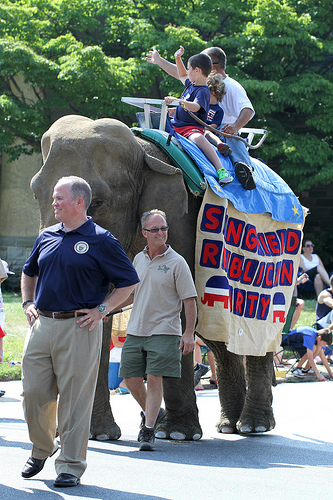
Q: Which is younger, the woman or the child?
A: The child is younger than the woman.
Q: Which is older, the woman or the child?
A: The woman is older than the child.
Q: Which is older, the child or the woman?
A: The woman is older than the child.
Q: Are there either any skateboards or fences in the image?
A: No, there are no fences or skateboards.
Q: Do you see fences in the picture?
A: No, there are no fences.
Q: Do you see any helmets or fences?
A: No, there are no fences or helmets.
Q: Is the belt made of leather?
A: Yes, the belt is made of leather.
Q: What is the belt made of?
A: The belt is made of leather.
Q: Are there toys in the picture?
A: No, there are no toys.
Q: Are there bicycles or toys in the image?
A: No, there are no toys or bicycles.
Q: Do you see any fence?
A: No, there are no fences.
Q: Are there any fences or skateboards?
A: No, there are no fences or skateboards.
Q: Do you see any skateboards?
A: No, there are no skateboards.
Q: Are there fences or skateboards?
A: No, there are no skateboards or fences.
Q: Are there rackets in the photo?
A: No, there are no rackets.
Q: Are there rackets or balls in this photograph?
A: No, there are no rackets or balls.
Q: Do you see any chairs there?
A: Yes, there is a chair.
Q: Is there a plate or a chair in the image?
A: Yes, there is a chair.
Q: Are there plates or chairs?
A: Yes, there is a chair.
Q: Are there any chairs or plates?
A: Yes, there is a chair.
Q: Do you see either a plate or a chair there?
A: Yes, there is a chair.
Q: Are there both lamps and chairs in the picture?
A: No, there is a chair but no lamps.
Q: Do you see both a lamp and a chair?
A: No, there is a chair but no lamps.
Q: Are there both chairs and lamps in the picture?
A: No, there is a chair but no lamps.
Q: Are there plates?
A: No, there are no plates.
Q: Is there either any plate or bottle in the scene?
A: No, there are no plates or bottles.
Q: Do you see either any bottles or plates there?
A: No, there are no plates or bottles.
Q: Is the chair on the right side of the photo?
A: Yes, the chair is on the right of the image.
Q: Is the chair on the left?
A: No, the chair is on the right of the image.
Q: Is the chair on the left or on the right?
A: The chair is on the right of the image.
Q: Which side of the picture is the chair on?
A: The chair is on the right of the image.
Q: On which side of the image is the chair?
A: The chair is on the right of the image.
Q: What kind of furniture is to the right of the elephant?
A: The piece of furniture is a chair.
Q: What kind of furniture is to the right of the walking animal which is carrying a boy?
A: The piece of furniture is a chair.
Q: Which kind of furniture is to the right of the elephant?
A: The piece of furniture is a chair.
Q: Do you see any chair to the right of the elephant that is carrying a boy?
A: Yes, there is a chair to the right of the elephant.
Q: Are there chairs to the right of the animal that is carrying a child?
A: Yes, there is a chair to the right of the elephant.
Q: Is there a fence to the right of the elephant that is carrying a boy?
A: No, there is a chair to the right of the elephant.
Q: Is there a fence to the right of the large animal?
A: No, there is a chair to the right of the elephant.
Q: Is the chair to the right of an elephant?
A: Yes, the chair is to the right of an elephant.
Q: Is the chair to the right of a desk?
A: No, the chair is to the right of an elephant.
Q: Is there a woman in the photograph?
A: Yes, there is a woman.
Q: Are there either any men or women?
A: Yes, there is a woman.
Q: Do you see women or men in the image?
A: Yes, there is a woman.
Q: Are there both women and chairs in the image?
A: Yes, there are both a woman and a chair.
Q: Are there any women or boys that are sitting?
A: Yes, the woman is sitting.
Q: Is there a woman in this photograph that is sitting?
A: Yes, there is a woman that is sitting.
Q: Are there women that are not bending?
A: Yes, there is a woman that is sitting.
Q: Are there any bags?
A: No, there are no bags.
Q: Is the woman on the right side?
A: Yes, the woman is on the right of the image.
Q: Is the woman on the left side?
A: No, the woman is on the right of the image.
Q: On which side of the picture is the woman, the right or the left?
A: The woman is on the right of the image.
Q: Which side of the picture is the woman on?
A: The woman is on the right of the image.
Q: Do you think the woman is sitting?
A: Yes, the woman is sitting.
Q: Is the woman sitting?
A: Yes, the woman is sitting.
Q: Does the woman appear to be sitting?
A: Yes, the woman is sitting.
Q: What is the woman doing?
A: The woman is sitting.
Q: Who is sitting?
A: The woman is sitting.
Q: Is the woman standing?
A: No, the woman is sitting.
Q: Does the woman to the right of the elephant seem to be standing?
A: No, the woman is sitting.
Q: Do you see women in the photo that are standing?
A: No, there is a woman but she is sitting.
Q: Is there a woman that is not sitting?
A: No, there is a woman but she is sitting.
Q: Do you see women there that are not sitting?
A: No, there is a woman but she is sitting.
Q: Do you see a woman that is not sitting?
A: No, there is a woman but she is sitting.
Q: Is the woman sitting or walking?
A: The woman is sitting.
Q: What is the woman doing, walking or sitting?
A: The woman is sitting.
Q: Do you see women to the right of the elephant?
A: Yes, there is a woman to the right of the elephant.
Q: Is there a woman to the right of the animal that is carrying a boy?
A: Yes, there is a woman to the right of the elephant.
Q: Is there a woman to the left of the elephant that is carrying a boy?
A: No, the woman is to the right of the elephant.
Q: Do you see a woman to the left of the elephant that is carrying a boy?
A: No, the woman is to the right of the elephant.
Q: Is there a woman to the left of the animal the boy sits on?
A: No, the woman is to the right of the elephant.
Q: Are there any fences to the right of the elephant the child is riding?
A: No, there is a woman to the right of the elephant.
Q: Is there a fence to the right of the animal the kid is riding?
A: No, there is a woman to the right of the elephant.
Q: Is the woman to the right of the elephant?
A: Yes, the woman is to the right of the elephant.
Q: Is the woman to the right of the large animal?
A: Yes, the woman is to the right of the elephant.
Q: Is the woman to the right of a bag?
A: No, the woman is to the right of the elephant.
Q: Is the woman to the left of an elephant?
A: No, the woman is to the right of an elephant.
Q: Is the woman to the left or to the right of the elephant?
A: The woman is to the right of the elephant.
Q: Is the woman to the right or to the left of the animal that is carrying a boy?
A: The woman is to the right of the elephant.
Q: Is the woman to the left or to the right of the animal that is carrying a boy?
A: The woman is to the right of the elephant.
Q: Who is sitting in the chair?
A: The woman is sitting in the chair.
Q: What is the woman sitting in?
A: The woman is sitting in the chair.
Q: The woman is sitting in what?
A: The woman is sitting in the chair.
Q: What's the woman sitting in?
A: The woman is sitting in the chair.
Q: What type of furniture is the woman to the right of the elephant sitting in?
A: The woman is sitting in the chair.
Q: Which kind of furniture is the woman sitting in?
A: The woman is sitting in the chair.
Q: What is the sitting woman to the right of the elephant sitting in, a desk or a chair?
A: The woman is sitting in a chair.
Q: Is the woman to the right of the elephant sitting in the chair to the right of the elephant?
A: Yes, the woman is sitting in the chair.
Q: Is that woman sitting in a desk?
A: No, the woman is sitting in the chair.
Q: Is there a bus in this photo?
A: No, there are no buses.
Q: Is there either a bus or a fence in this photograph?
A: No, there are no buses or fences.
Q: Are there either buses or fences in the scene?
A: No, there are no buses or fences.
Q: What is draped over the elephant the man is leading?
A: The sign is draped over the elephant.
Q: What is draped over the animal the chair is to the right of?
A: The sign is draped over the elephant.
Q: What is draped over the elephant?
A: The sign is draped over the elephant.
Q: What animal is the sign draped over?
A: The sign is draped over the elephant.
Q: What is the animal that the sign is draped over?
A: The animal is an elephant.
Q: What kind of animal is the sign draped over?
A: The sign is draped over the elephant.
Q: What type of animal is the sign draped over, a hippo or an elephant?
A: The sign is draped over an elephant.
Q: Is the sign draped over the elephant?
A: Yes, the sign is draped over the elephant.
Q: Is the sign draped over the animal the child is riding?
A: Yes, the sign is draped over the elephant.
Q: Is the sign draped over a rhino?
A: No, the sign is draped over the elephant.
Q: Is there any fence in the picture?
A: No, there are no fences.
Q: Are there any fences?
A: No, there are no fences.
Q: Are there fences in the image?
A: No, there are no fences.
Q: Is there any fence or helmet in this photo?
A: No, there are no fences or helmets.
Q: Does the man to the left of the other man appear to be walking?
A: Yes, the man is walking.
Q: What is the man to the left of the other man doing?
A: The man is walking.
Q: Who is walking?
A: The man is walking.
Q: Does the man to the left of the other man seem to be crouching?
A: No, the man is walking.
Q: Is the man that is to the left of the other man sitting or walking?
A: The man is walking.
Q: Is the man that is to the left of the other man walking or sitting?
A: The man is walking.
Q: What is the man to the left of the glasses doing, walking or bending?
A: The man is walking.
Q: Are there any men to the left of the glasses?
A: Yes, there is a man to the left of the glasses.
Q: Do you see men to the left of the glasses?
A: Yes, there is a man to the left of the glasses.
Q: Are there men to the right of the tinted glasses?
A: No, the man is to the left of the glasses.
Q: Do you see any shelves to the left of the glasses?
A: No, there is a man to the left of the glasses.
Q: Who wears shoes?
A: The man wears shoes.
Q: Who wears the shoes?
A: The man wears shoes.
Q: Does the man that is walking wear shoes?
A: Yes, the man wears shoes.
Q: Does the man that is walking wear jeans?
A: No, the man wears shoes.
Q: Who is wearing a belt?
A: The man is wearing a belt.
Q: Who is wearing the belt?
A: The man is wearing a belt.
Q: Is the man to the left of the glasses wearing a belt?
A: Yes, the man is wearing a belt.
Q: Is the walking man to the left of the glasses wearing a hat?
A: No, the man is wearing a belt.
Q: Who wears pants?
A: The man wears pants.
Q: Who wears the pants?
A: The man wears pants.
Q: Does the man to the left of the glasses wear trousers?
A: Yes, the man wears trousers.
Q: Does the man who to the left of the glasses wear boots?
A: No, the man wears trousers.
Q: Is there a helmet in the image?
A: No, there are no helmets.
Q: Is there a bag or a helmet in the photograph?
A: No, there are no helmets or bags.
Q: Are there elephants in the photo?
A: Yes, there is an elephant.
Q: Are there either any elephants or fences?
A: Yes, there is an elephant.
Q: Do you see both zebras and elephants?
A: No, there is an elephant but no zebras.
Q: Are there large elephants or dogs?
A: Yes, there is a large elephant.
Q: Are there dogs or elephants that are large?
A: Yes, the elephant is large.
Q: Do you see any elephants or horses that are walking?
A: Yes, the elephant is walking.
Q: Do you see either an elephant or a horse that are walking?
A: Yes, the elephant is walking.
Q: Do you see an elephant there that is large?
A: Yes, there is a large elephant.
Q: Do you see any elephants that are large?
A: Yes, there is an elephant that is large.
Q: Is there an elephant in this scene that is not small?
A: Yes, there is a large elephant.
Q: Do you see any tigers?
A: No, there are no tigers.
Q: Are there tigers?
A: No, there are no tigers.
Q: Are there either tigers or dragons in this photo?
A: No, there are no tigers or dragons.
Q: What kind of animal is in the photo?
A: The animal is an elephant.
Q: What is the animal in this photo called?
A: The animal is an elephant.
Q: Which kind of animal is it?
A: The animal is an elephant.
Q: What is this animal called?
A: This is an elephant.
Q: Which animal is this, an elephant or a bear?
A: This is an elephant.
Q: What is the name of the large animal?
A: The animal is an elephant.